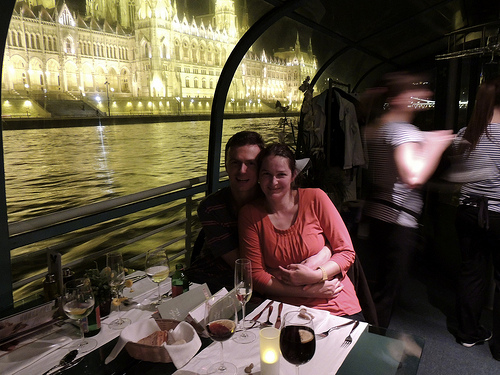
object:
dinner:
[64, 247, 368, 375]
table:
[0, 269, 425, 374]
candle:
[258, 325, 281, 373]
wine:
[280, 323, 319, 367]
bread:
[136, 327, 170, 345]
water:
[1, 108, 298, 320]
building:
[2, 0, 319, 118]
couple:
[188, 130, 365, 323]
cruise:
[3, 3, 500, 374]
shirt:
[239, 187, 363, 317]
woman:
[447, 76, 500, 347]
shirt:
[451, 119, 499, 213]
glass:
[229, 258, 256, 344]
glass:
[142, 249, 171, 302]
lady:
[357, 76, 465, 229]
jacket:
[306, 86, 366, 203]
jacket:
[337, 86, 366, 132]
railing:
[1, 170, 229, 318]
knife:
[250, 298, 274, 322]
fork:
[340, 321, 365, 348]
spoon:
[261, 303, 274, 326]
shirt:
[193, 180, 265, 247]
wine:
[201, 318, 242, 342]